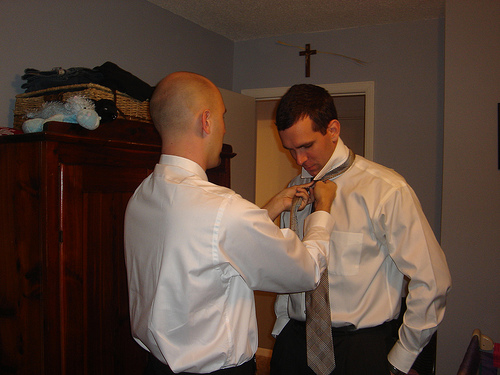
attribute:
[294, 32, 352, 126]
cross — hanging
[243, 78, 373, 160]
frame — white, wooden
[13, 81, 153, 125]
basket — wicker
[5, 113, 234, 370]
armoire — wooden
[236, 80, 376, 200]
door — open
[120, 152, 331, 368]
dress shirt — white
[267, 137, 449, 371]
dress shirt — white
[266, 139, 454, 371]
shirt — white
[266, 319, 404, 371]
pants — black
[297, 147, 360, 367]
tie — gray, plaid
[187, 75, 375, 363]
doorway — open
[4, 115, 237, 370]
armoir — dark, wood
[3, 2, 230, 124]
wall — blue, painted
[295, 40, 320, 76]
cross — wooden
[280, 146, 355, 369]
tie — gray, plaid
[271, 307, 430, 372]
pants — black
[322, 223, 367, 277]
pocket — white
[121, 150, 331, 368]
shirt — white, long sleeve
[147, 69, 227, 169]
head — bald, shaved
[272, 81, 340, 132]
hair — dark, brown